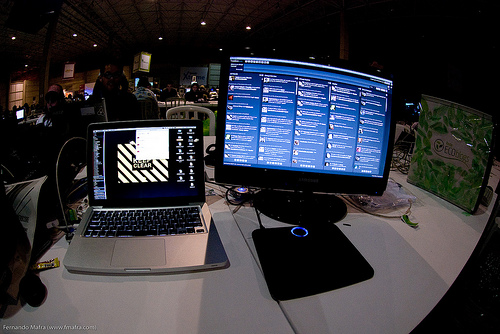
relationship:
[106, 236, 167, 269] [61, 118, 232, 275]
track pad on laptop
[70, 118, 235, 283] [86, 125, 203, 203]
laptop has screen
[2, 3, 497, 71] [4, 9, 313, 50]
ceiling has lights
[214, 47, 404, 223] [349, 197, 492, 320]
computer on desk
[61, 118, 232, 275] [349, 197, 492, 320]
laptop on desk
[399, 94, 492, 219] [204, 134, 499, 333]
binder on table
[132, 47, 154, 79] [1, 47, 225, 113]
poster on wall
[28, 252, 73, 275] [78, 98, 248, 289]
candy next to laptop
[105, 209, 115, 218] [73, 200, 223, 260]
key on keyboard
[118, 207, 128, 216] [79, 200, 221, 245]
key on keyboard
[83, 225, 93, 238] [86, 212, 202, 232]
key on keyboard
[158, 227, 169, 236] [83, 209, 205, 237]
black key on keyboard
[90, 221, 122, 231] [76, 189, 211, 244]
key on keyboard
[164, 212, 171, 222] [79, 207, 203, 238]
key on keyboard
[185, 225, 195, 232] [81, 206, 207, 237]
black key on keyboard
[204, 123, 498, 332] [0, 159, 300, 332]
table next to table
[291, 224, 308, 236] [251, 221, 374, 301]
part on touch pad